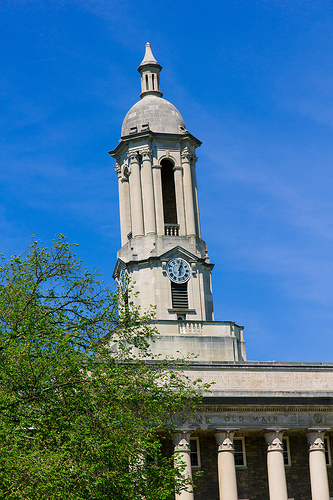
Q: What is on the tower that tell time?
A: Clock.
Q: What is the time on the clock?
A: 6:05.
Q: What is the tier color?
A: Beige.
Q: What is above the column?
A: Writing.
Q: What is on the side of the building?
A: Trees.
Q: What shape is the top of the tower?
A: Triangle.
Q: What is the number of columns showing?
A: 5.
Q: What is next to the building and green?
A: Tree.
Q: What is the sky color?
A: Blue.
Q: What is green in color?
A: The trees.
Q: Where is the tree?
A: On the ground.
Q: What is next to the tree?
A: A building.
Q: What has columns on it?
A: The old building.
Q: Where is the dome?
A: On the tower.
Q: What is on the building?
A: A clock.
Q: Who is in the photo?
A: No people.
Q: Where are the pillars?
A: On the building.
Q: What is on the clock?
A: Hands.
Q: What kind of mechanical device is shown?
A: A clock.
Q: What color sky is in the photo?
A: Blue.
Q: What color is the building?
A: White.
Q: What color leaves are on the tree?
A: Green.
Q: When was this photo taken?
A: Daytime.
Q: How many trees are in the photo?
A: One.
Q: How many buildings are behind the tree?
A: One.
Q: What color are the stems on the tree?
A: Brown.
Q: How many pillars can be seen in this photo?
A: Five.